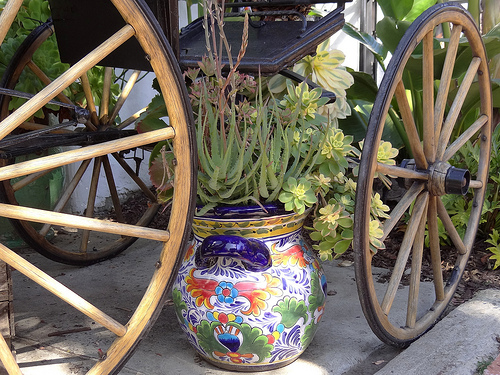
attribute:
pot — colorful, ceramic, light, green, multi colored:
[168, 202, 332, 370]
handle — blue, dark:
[194, 231, 270, 272]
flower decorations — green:
[190, 316, 272, 362]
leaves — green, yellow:
[485, 227, 499, 263]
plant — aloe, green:
[183, 48, 397, 255]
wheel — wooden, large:
[355, 5, 492, 348]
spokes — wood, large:
[428, 27, 482, 157]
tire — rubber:
[354, 78, 389, 343]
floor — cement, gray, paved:
[10, 295, 499, 370]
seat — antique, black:
[173, 19, 342, 64]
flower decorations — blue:
[206, 259, 256, 280]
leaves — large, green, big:
[348, 8, 412, 142]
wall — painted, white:
[319, 5, 394, 118]